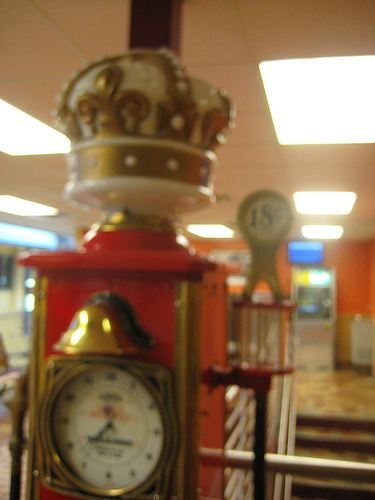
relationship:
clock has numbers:
[34, 347, 186, 498] [61, 368, 161, 478]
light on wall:
[257, 55, 374, 146] [288, 245, 373, 282]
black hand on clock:
[88, 415, 114, 440] [43, 362, 166, 493]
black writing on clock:
[87, 436, 131, 446] [43, 362, 166, 493]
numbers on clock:
[51, 390, 84, 462] [40, 333, 183, 494]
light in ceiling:
[293, 191, 357, 215] [0, 2, 373, 242]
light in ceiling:
[299, 222, 342, 242] [0, 2, 373, 242]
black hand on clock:
[74, 421, 110, 455] [34, 347, 186, 498]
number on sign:
[250, 202, 273, 227] [235, 190, 291, 253]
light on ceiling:
[257, 55, 374, 146] [233, 35, 332, 161]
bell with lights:
[46, 289, 166, 359] [66, 309, 114, 345]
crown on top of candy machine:
[53, 45, 235, 215] [9, 209, 295, 498]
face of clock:
[49, 367, 162, 491] [34, 347, 186, 498]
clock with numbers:
[34, 347, 186, 498] [94, 463, 115, 486]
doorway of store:
[265, 250, 352, 383] [54, 92, 349, 357]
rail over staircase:
[202, 441, 373, 481] [292, 413, 374, 498]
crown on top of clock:
[57, 38, 222, 216] [6, 232, 293, 496]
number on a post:
[236, 185, 290, 234] [227, 188, 296, 359]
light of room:
[2, 50, 373, 255] [4, 10, 372, 499]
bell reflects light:
[53, 292, 157, 356] [2, 50, 373, 255]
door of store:
[286, 256, 343, 355] [0, 0, 373, 499]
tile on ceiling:
[3, 5, 126, 62] [0, 2, 373, 242]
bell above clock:
[53, 292, 157, 356] [43, 362, 166, 493]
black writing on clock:
[83, 430, 136, 449] [43, 362, 166, 493]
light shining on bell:
[63, 306, 104, 356] [47, 278, 160, 370]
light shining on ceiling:
[1, 191, 61, 227] [0, 2, 373, 242]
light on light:
[291, 188, 361, 219] [301, 223, 350, 242]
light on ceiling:
[291, 188, 361, 219] [0, 2, 373, 242]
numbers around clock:
[46, 355, 184, 496] [36, 345, 194, 491]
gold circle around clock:
[32, 353, 177, 499] [43, 362, 166, 493]